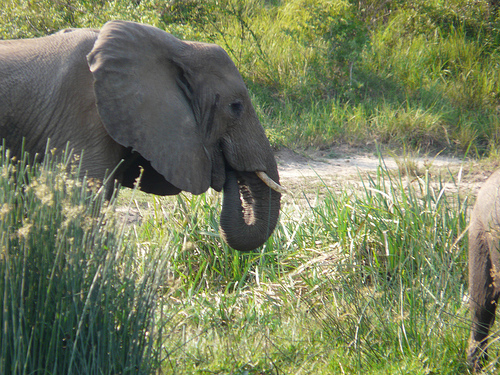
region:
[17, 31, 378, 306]
the elephant is eating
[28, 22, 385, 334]
the elephant is gray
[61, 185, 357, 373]
the grasses are tall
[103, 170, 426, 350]
the grasses are green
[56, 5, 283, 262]
elephant's ears are wide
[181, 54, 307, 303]
the elephant is wrinkled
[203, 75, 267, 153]
elephant's eye is black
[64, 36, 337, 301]
the elephant has tusks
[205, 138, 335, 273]
the trunk is in the mouth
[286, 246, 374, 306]
dry grass on the ground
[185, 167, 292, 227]
The elephant's trunk is in it's mouth.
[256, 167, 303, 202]
The tusk is white.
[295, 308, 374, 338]
The grass is green.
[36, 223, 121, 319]
The weeds are tall.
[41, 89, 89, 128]
The elephant is grey.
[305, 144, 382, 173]
Dirt patch on the ground.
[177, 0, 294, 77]
Twig behind the elephant.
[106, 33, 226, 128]
The ear is big.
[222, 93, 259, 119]
The eye is small.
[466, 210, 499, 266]
Another elephant in front.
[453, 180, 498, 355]
the elephant is small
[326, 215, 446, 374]
the grass is green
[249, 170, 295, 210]
the task are white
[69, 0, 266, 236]
the trunk is in the mouth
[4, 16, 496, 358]
the photo was taken outdoors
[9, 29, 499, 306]
there are two elephants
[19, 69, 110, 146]
the skin is wrinkled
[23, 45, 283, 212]
the elephant is grey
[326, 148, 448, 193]
the path has no grass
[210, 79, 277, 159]
the eye is open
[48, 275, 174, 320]
long blades of green grass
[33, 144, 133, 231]
purple buds on green grass buds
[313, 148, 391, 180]
bare sand on ground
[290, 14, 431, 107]
cluster of green grass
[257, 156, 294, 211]
short tan tusk on elephant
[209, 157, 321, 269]
up turned gray elephant's tusk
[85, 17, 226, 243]
large floppy elephant's ear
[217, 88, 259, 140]
small black eyes on elephant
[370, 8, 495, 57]
tree trunk on ground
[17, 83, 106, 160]
lines on elephant's back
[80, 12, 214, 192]
Elephants right ear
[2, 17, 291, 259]
large elephant eating grass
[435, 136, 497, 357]
Back leg of another elephant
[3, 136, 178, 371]
Patch of grass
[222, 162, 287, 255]
The elephant's trunk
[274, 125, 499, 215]
Dirt road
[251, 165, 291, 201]
Right tusk of an elephant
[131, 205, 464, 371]
Long green grass, food for the elephant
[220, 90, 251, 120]
Right eye of an elephant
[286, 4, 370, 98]
Small shrub in the brush